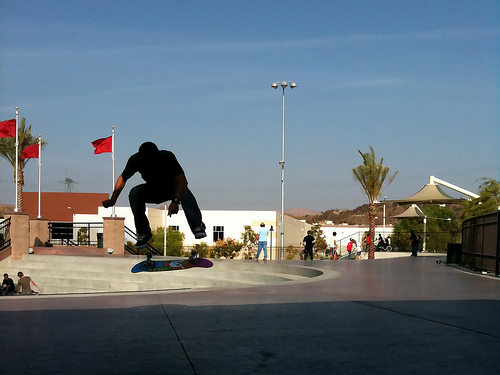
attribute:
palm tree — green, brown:
[335, 130, 417, 259]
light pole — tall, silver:
[266, 64, 328, 266]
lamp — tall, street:
[273, 73, 312, 258]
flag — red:
[0, 117, 15, 136]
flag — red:
[19, 143, 39, 158]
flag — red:
[90, 135, 112, 155]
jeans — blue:
[257, 241, 268, 262]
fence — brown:
[43, 213, 144, 268]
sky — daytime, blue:
[152, 22, 277, 87]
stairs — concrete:
[38, 252, 137, 290]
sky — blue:
[0, 1, 498, 202]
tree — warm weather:
[351, 143, 400, 267]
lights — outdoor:
[266, 74, 310, 184]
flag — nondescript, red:
[90, 134, 110, 155]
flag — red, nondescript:
[20, 139, 38, 156]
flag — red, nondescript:
[1, 118, 17, 134]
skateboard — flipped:
[124, 240, 214, 275]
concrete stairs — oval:
[3, 252, 325, 299]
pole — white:
[425, 171, 487, 203]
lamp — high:
[271, 79, 299, 261]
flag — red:
[7, 97, 104, 216]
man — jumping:
[103, 141, 207, 248]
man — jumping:
[96, 140, 208, 260]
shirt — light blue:
[245, 223, 280, 243]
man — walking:
[256, 220, 273, 263]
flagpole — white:
[34, 139, 43, 218]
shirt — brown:
[19, 274, 29, 291]